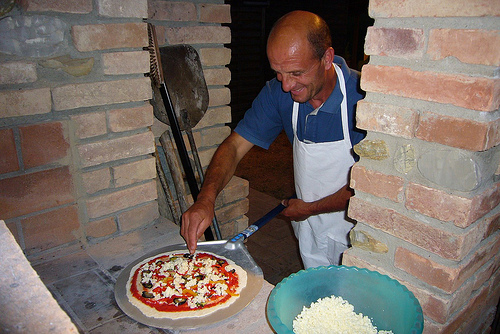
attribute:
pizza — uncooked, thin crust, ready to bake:
[125, 247, 250, 322]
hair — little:
[306, 19, 334, 62]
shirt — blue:
[233, 56, 366, 150]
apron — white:
[288, 64, 355, 266]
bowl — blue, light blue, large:
[264, 263, 425, 334]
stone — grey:
[33, 218, 265, 333]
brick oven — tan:
[0, 219, 81, 333]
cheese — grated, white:
[307, 311, 354, 333]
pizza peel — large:
[113, 206, 264, 333]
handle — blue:
[252, 202, 281, 231]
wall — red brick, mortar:
[1, 0, 152, 215]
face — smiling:
[267, 42, 317, 102]